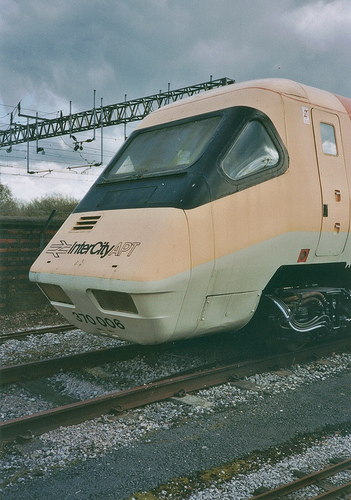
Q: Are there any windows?
A: Yes, there is a window.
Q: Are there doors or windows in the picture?
A: Yes, there is a window.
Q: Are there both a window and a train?
A: Yes, there are both a window and a train.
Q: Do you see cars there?
A: No, there are no cars.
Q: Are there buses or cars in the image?
A: No, there are no cars or buses.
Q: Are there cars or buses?
A: No, there are no cars or buses.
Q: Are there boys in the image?
A: No, there are no boys.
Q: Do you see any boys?
A: No, there are no boys.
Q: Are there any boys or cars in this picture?
A: No, there are no boys or cars.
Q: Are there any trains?
A: Yes, there is a train.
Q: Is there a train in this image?
A: Yes, there is a train.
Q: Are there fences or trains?
A: Yes, there is a train.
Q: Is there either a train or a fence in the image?
A: Yes, there is a train.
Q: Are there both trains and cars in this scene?
A: No, there is a train but no cars.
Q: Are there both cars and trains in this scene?
A: No, there is a train but no cars.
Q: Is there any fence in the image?
A: No, there are no fences.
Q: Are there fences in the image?
A: No, there are no fences.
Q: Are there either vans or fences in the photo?
A: No, there are no fences or vans.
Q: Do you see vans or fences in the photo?
A: No, there are no fences or vans.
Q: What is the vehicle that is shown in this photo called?
A: The vehicle is a train.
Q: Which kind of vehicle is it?
A: The vehicle is a train.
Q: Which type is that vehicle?
A: This is a train.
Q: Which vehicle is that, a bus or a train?
A: This is a train.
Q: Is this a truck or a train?
A: This is a train.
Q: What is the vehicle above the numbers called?
A: The vehicle is a train.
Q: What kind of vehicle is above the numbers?
A: The vehicle is a train.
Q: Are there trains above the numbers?
A: Yes, there is a train above the numbers.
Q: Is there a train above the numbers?
A: Yes, there is a train above the numbers.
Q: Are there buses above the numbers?
A: No, there is a train above the numbers.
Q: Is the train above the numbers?
A: Yes, the train is above the numbers.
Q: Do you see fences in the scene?
A: No, there are no fences.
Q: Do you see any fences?
A: No, there are no fences.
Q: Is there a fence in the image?
A: No, there are no fences.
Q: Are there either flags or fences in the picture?
A: No, there are no fences or flags.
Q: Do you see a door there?
A: Yes, there is a door.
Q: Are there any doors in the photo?
A: Yes, there is a door.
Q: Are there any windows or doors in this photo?
A: Yes, there is a door.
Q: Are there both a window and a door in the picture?
A: Yes, there are both a door and a window.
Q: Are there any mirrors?
A: No, there are no mirrors.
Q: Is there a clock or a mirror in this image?
A: No, there are no mirrors or clocks.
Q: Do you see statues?
A: No, there are no statues.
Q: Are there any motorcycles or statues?
A: No, there are no statues or motorcycles.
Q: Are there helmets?
A: No, there are no helmets.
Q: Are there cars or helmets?
A: No, there are no helmets or cars.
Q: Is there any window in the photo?
A: Yes, there is a window.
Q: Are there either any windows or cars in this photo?
A: Yes, there is a window.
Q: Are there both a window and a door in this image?
A: Yes, there are both a window and a door.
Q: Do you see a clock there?
A: No, there are no clocks.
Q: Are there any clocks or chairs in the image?
A: No, there are no clocks or chairs.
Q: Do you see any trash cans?
A: No, there are no trash cans.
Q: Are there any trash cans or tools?
A: No, there are no trash cans or tools.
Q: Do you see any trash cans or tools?
A: No, there are no trash cans or tools.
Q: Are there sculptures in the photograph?
A: No, there are no sculptures.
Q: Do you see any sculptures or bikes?
A: No, there are no sculptures or bikes.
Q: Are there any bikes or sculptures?
A: No, there are no sculptures or bikes.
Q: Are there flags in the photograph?
A: No, there are no flags.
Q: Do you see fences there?
A: No, there are no fences.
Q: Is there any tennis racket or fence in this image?
A: No, there are no fences or rackets.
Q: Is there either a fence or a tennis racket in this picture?
A: No, there are no fences or rackets.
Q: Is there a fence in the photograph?
A: No, there are no fences.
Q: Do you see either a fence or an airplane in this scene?
A: No, there are no fences or airplanes.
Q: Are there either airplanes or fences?
A: No, there are no fences or airplanes.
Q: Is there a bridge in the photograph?
A: Yes, there is a bridge.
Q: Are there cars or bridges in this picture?
A: Yes, there is a bridge.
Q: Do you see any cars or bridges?
A: Yes, there is a bridge.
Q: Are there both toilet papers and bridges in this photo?
A: No, there is a bridge but no toilet papers.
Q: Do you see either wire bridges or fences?
A: Yes, there is a wire bridge.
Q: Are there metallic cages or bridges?
A: Yes, there is a metal bridge.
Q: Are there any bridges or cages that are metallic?
A: Yes, the bridge is metallic.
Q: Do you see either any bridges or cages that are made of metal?
A: Yes, the bridge is made of metal.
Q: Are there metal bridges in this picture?
A: Yes, there is a metal bridge.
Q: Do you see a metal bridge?
A: Yes, there is a metal bridge.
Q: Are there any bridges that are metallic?
A: Yes, there is a bridge that is metallic.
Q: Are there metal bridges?
A: Yes, there is a bridge that is made of metal.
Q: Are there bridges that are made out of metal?
A: Yes, there is a bridge that is made of metal.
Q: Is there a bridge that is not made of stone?
A: Yes, there is a bridge that is made of metal.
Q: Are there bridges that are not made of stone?
A: Yes, there is a bridge that is made of metal.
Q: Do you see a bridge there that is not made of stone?
A: Yes, there is a bridge that is made of metal.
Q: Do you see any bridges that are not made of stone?
A: Yes, there is a bridge that is made of metal.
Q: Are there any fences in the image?
A: No, there are no fences.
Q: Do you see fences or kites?
A: No, there are no fences or kites.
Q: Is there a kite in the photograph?
A: No, there are no kites.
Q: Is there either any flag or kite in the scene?
A: No, there are no kites or flags.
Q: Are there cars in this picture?
A: No, there are no cars.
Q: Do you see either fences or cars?
A: No, there are no cars or fences.